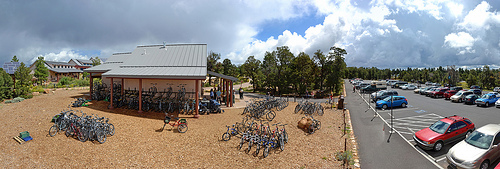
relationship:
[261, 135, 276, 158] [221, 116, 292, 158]
bikes on a rack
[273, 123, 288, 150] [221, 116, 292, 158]
bikes on a rack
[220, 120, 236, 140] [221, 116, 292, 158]
bikes on a rack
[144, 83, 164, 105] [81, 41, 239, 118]
bike under a building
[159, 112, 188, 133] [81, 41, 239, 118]
bike under a building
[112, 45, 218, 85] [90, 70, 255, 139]
wall on building